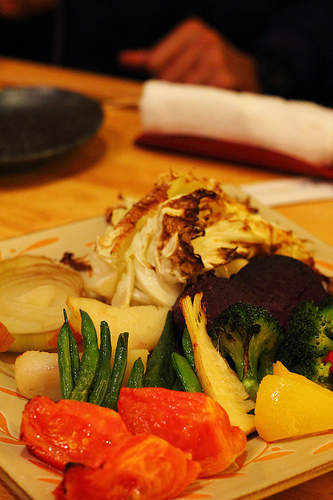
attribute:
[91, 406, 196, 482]
tomatoes — sliced, red, roasted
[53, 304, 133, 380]
beans — fresh, green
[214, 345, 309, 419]
lemon — yellow, bright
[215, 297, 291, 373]
broccoli — roasted, green, spears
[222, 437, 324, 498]
plate — square, outer, white, orange, circular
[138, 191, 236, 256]
cabbage — chunked, chinese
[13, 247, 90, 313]
onion — roasted, half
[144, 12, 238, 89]
man — white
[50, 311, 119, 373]
snow pea — roasted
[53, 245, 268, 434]
vegetables — roasted, grilled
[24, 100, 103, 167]
pan — behind, black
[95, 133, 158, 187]
table — wooden, yellow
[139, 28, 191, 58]
hand — over, back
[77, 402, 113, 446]
fish — fresh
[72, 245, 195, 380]
potatoes — fresh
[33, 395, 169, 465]
food — yellow, red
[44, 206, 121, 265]
dish — colored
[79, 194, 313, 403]
veggies — grilled